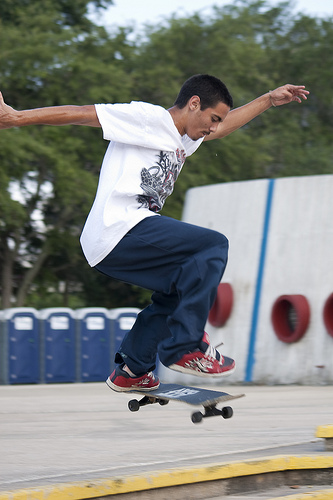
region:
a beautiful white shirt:
[103, 105, 190, 249]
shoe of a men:
[103, 359, 161, 393]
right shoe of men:
[179, 336, 239, 372]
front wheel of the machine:
[187, 411, 245, 422]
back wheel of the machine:
[123, 392, 154, 416]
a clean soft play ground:
[7, 383, 331, 463]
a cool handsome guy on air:
[28, 44, 269, 468]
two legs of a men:
[141, 220, 233, 371]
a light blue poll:
[240, 175, 276, 398]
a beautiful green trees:
[14, 9, 330, 102]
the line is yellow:
[222, 466, 233, 485]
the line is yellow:
[194, 472, 205, 482]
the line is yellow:
[167, 469, 181, 493]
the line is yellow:
[171, 470, 188, 494]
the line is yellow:
[182, 474, 191, 479]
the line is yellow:
[171, 475, 178, 482]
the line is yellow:
[175, 478, 183, 486]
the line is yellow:
[176, 475, 186, 487]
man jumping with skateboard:
[74, 67, 312, 406]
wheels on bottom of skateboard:
[125, 395, 235, 424]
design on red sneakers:
[179, 356, 222, 375]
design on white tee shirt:
[133, 150, 193, 216]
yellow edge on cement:
[185, 457, 272, 484]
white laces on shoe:
[203, 343, 220, 365]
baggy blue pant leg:
[147, 215, 215, 366]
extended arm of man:
[227, 78, 313, 133]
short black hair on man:
[168, 72, 232, 120]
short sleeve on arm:
[45, 98, 142, 146]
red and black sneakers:
[99, 306, 255, 418]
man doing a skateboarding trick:
[26, 42, 314, 432]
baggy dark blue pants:
[53, 205, 245, 429]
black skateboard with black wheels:
[107, 343, 251, 468]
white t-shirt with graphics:
[82, 96, 250, 340]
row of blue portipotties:
[4, 289, 211, 434]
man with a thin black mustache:
[129, 59, 239, 198]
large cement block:
[6, 385, 324, 491]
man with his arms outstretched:
[1, 43, 322, 232]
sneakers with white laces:
[160, 316, 273, 425]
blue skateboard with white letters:
[130, 379, 235, 424]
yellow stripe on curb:
[74, 456, 318, 491]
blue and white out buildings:
[5, 299, 89, 382]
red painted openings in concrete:
[268, 286, 309, 353]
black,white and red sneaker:
[107, 356, 165, 394]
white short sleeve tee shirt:
[77, 89, 214, 274]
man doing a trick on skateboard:
[6, 54, 250, 484]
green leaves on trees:
[43, 144, 74, 197]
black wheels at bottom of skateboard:
[126, 392, 238, 423]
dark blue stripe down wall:
[251, 200, 281, 376]